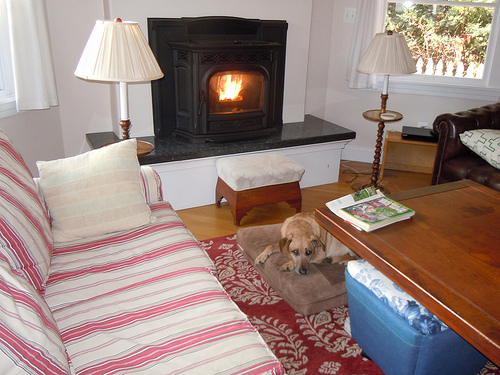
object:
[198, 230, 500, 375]
carpet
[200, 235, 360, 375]
white flowers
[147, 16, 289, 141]
fireplace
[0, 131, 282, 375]
cloth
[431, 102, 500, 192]
couch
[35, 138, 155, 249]
pillow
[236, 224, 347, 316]
cushion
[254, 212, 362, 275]
dog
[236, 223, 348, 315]
pillow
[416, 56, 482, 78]
fence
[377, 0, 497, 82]
window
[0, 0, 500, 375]
living room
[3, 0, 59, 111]
curtain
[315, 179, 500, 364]
table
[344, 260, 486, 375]
basket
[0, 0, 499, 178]
wall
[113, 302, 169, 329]
line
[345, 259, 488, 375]
container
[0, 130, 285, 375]
cushion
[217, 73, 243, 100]
fire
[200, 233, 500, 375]
rug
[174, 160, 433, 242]
floor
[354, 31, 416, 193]
lamp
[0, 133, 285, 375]
couch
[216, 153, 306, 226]
stool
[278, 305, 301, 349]
part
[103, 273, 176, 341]
part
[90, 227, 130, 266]
part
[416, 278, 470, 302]
part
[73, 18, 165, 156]
lamp